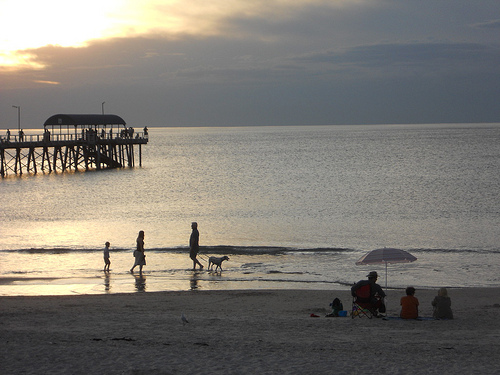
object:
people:
[351, 270, 455, 322]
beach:
[0, 286, 500, 373]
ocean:
[0, 122, 500, 298]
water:
[158, 166, 223, 205]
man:
[188, 220, 202, 273]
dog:
[207, 254, 231, 273]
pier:
[0, 105, 154, 179]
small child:
[102, 241, 110, 273]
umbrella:
[354, 247, 415, 265]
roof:
[46, 114, 138, 126]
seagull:
[176, 307, 199, 330]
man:
[142, 126, 150, 142]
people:
[6, 126, 150, 145]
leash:
[197, 251, 212, 267]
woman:
[129, 231, 147, 278]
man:
[349, 270, 388, 319]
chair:
[353, 300, 386, 315]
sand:
[428, 353, 478, 365]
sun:
[0, 0, 135, 50]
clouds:
[164, 0, 500, 67]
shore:
[457, 275, 496, 305]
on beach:
[234, 306, 289, 338]